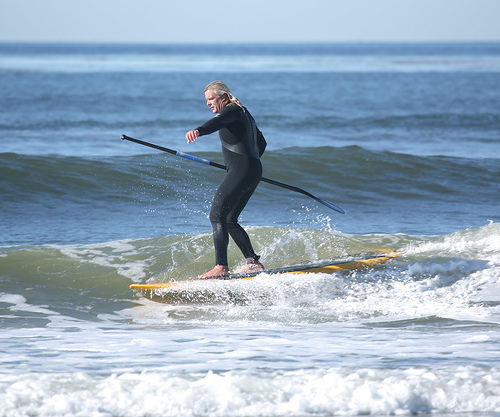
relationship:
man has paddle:
[186, 81, 268, 278] [118, 133, 345, 222]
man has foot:
[186, 81, 268, 278] [201, 264, 226, 279]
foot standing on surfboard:
[237, 258, 262, 276] [124, 249, 404, 297]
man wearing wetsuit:
[186, 81, 268, 278] [199, 102, 266, 263]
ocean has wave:
[1, 42, 496, 417] [1, 151, 499, 225]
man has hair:
[186, 81, 268, 278] [204, 81, 243, 112]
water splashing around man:
[137, 154, 343, 276] [186, 81, 268, 278]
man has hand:
[186, 81, 268, 278] [183, 130, 199, 143]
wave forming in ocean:
[1, 151, 499, 225] [1, 42, 496, 417]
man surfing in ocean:
[186, 81, 268, 278] [1, 42, 496, 417]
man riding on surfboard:
[186, 81, 268, 278] [124, 249, 404, 297]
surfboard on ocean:
[124, 249, 404, 297] [1, 42, 496, 417]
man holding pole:
[186, 81, 268, 278] [118, 132, 317, 210]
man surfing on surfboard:
[186, 81, 268, 278] [124, 249, 404, 297]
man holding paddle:
[186, 81, 268, 278] [118, 133, 345, 222]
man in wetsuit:
[186, 81, 268, 278] [199, 102, 266, 263]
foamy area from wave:
[2, 233, 495, 415] [1, 151, 499, 225]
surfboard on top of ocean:
[124, 249, 404, 297] [1, 42, 496, 417]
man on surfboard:
[186, 81, 268, 278] [124, 249, 404, 297]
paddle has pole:
[118, 133, 345, 222] [118, 132, 317, 210]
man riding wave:
[186, 81, 268, 278] [1, 151, 499, 225]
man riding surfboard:
[186, 81, 268, 278] [124, 249, 404, 297]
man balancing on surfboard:
[186, 81, 268, 278] [124, 249, 404, 297]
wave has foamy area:
[1, 151, 499, 225] [2, 233, 495, 415]